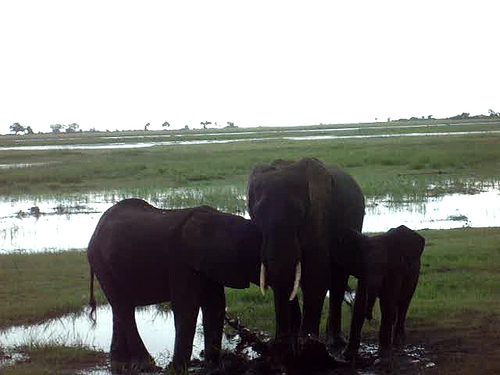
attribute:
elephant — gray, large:
[252, 166, 348, 359]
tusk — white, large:
[291, 262, 307, 305]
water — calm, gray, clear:
[41, 225, 60, 237]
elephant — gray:
[91, 200, 253, 369]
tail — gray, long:
[83, 268, 102, 320]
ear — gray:
[180, 211, 252, 289]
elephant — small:
[361, 217, 413, 357]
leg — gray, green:
[303, 283, 322, 347]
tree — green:
[11, 120, 22, 133]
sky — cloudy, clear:
[138, 10, 177, 41]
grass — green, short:
[458, 289, 479, 308]